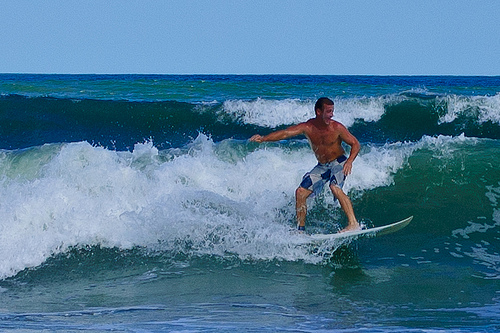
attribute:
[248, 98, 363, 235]
man — wet, shirtless, surfing, alone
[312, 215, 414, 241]
surfboard — wet, white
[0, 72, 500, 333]
water — splashing, wavy, zealous, blue, green, beautiful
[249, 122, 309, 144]
right arm — outstretched, extended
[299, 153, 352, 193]
shorts — patterned, blue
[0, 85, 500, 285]
waves — breaking, white, cresting, large, foamy, crashing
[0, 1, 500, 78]
sky — bright blue, cloudless, light blue, blue, clear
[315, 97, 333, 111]
hair — short, brown